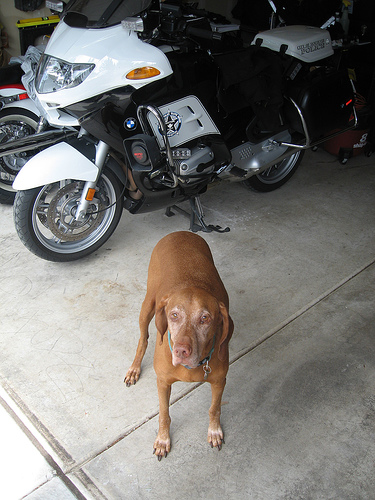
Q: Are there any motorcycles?
A: Yes, there is a motorcycle.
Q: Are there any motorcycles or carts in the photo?
A: Yes, there is a motorcycle.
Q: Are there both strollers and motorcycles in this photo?
A: No, there is a motorcycle but no strollers.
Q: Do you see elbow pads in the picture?
A: No, there are no elbow pads.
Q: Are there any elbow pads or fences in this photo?
A: No, there are no elbow pads or fences.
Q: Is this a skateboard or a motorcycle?
A: This is a motorcycle.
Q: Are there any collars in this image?
A: Yes, there is a collar.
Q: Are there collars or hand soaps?
A: Yes, there is a collar.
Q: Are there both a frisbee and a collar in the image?
A: No, there is a collar but no frisbees.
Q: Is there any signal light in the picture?
A: No, there are no traffic lights.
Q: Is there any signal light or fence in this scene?
A: No, there are no traffic lights or fences.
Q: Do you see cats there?
A: No, there are no cats.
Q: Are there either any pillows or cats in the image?
A: No, there are no cats or pillows.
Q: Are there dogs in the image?
A: Yes, there is a dog.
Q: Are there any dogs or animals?
A: Yes, there is a dog.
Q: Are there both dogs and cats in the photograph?
A: No, there is a dog but no cats.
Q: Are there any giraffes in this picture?
A: No, there are no giraffes.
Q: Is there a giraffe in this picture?
A: No, there are no giraffes.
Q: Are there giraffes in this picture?
A: No, there are no giraffes.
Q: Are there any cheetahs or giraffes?
A: No, there are no giraffes or cheetahs.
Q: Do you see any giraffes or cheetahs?
A: No, there are no giraffes or cheetahs.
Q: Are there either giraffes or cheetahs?
A: No, there are no giraffes or cheetahs.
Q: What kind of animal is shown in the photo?
A: The animal is a dog.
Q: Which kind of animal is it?
A: The animal is a dog.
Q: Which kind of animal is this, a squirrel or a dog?
A: This is a dog.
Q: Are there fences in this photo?
A: No, there are no fences.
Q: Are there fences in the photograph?
A: No, there are no fences.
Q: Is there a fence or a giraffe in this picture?
A: No, there are no fences or giraffes.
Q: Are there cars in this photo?
A: No, there are no cars.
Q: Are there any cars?
A: No, there are no cars.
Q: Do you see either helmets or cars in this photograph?
A: No, there are no cars or helmets.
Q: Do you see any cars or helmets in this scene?
A: No, there are no cars or helmets.